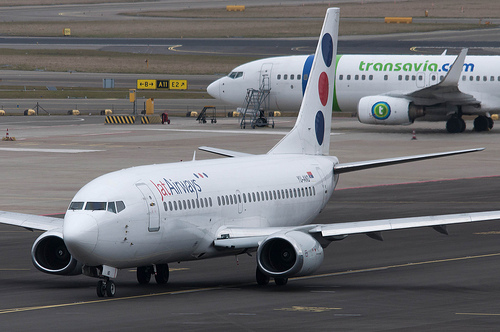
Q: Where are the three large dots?
A: On the tail of the plane.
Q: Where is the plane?
A: On the runway.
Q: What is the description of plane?
A: White.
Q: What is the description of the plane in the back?
A: White, green and blue.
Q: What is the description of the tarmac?
A: Light gray.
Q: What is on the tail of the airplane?
A: Three dots.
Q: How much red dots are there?
A: One.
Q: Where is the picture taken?
A: An airport.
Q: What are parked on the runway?
A: Planes.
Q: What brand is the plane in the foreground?
A: Jat airways.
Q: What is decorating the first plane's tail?
A: Red and blue dots.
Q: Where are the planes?
A: On the tarmac.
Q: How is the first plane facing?
A: Straight ahead.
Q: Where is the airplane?
A: Runway.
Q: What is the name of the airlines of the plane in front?
A: Jat Airways.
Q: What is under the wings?
A: Engine.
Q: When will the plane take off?
A: When all passengers board.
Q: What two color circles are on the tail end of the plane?
A: Blue and red.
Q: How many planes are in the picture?
A: Two.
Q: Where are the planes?
A: Airport.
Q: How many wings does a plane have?
A: Four.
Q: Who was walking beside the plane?
A: No one.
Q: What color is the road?
A: Black.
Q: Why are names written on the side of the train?
A: Different airlines.